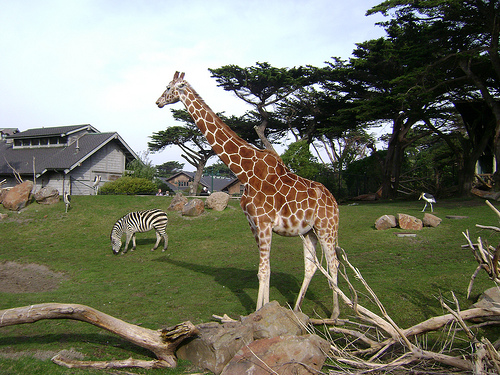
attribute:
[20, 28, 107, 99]
sky — very light, blue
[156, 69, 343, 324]
adult giraffe — fully grown